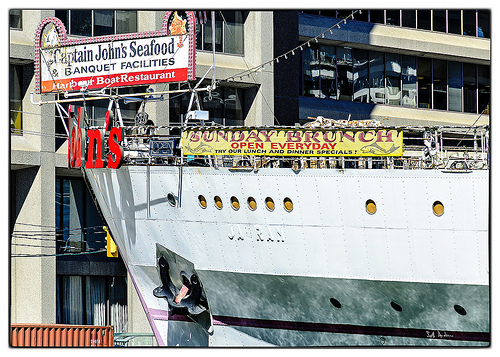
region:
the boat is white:
[222, 107, 382, 302]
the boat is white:
[269, 108, 464, 320]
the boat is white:
[239, 121, 410, 241]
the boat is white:
[255, 84, 343, 266]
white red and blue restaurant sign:
[31, 11, 198, 98]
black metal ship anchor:
[150, 256, 220, 336]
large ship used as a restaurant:
[38, 8, 495, 349]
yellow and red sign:
[175, 119, 409, 160]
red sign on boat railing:
[61, 100, 129, 174]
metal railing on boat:
[58, 117, 497, 173]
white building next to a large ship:
[1, 0, 285, 355]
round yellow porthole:
[363, 197, 380, 217]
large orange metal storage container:
[9, 320, 117, 349]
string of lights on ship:
[56, 6, 380, 117]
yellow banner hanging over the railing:
[178, 123, 405, 165]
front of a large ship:
[46, 101, 493, 356]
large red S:
[106, 128, 126, 169]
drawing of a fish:
[361, 138, 402, 156]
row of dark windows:
[294, 38, 482, 108]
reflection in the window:
[307, 48, 420, 98]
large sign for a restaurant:
[19, 10, 216, 95]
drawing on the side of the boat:
[136, 242, 242, 337]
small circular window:
[359, 196, 380, 216]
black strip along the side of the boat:
[221, 313, 481, 341]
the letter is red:
[69, 98, 119, 175]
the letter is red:
[45, 100, 175, 191]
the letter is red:
[71, 110, 228, 261]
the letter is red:
[80, 123, 145, 173]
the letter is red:
[31, 95, 134, 158]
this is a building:
[13, 123, 53, 308]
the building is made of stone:
[24, 190, 48, 218]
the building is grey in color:
[31, 191, 48, 217]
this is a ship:
[45, 57, 483, 342]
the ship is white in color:
[306, 220, 364, 267]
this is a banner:
[183, 124, 405, 156]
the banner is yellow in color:
[213, 141, 223, 147]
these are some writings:
[187, 127, 398, 154]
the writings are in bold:
[192, 131, 397, 144]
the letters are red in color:
[76, 130, 115, 165]